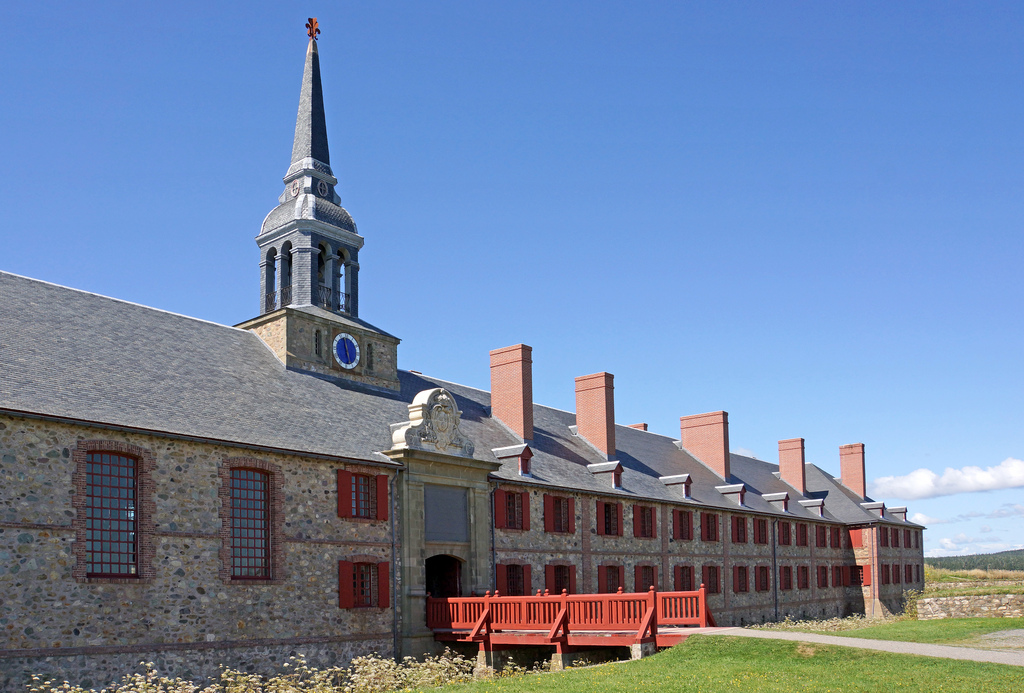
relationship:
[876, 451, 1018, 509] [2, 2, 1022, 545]
clouds are in sky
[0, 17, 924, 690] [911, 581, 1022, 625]
church has wall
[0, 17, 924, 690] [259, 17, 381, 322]
church has a tower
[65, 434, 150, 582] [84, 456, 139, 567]
window has safety bars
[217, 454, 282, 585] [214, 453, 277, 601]
windows has frame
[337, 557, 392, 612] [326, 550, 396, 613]
window has frame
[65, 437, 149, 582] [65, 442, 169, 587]
window has frame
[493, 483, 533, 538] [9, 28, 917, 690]
window on front of church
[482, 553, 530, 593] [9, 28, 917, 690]
window on front of church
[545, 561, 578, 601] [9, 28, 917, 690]
window on front of church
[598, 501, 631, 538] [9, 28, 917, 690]
window on front of church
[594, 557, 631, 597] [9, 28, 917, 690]
window on front of church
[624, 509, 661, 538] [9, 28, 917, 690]
window on front of church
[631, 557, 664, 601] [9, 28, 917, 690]
window on front of church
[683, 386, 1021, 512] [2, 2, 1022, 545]
clouds in sky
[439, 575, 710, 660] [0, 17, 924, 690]
bridge on church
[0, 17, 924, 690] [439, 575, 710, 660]
church with bridge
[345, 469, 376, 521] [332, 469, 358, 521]
window has shutter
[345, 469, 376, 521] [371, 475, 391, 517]
window has shutter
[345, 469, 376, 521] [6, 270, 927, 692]
window on building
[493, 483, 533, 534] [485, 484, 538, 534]
window with shutters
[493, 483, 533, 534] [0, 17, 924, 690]
window on church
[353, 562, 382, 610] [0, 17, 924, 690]
window adorning church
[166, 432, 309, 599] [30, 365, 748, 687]
windows on building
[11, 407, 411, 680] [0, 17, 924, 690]
wall on church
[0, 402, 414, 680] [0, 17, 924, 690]
wall on church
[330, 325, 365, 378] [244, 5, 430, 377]
clock on tower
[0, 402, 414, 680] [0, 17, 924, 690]
wall supporting church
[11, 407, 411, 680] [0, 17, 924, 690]
wall supporting church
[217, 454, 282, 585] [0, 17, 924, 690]
windows on a church